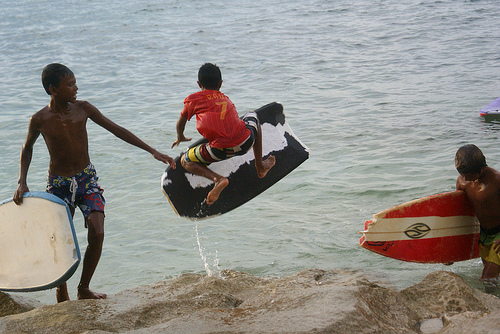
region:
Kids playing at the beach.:
[43, 65, 498, 269]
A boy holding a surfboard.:
[339, 132, 494, 266]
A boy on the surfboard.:
[165, 65, 279, 203]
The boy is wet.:
[17, 74, 127, 206]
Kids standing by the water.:
[30, 80, 463, 327]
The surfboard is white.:
[8, 186, 103, 303]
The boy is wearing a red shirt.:
[188, 85, 245, 140]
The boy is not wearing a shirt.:
[25, 101, 115, 174]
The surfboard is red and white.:
[343, 193, 483, 275]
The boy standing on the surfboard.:
[159, 75, 319, 209]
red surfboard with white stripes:
[356, 188, 484, 263]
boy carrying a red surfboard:
[361, 143, 498, 267]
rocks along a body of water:
[2, 271, 495, 330]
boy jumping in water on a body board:
[160, 63, 310, 220]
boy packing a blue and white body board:
[0, 60, 172, 298]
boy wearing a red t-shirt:
[180, 90, 250, 150]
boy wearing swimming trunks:
[44, 163, 104, 224]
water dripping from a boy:
[191, 219, 225, 279]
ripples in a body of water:
[302, 3, 452, 125]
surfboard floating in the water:
[476, 98, 498, 122]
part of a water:
[345, 46, 375, 121]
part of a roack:
[320, 270, 339, 292]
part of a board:
[381, 210, 421, 280]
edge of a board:
[356, 183, 390, 258]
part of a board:
[221, 159, 258, 216]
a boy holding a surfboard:
[5, 50, 121, 296]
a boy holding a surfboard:
[319, 93, 487, 329]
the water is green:
[249, 42, 354, 108]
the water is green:
[268, 218, 355, 264]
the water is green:
[288, 44, 384, 61]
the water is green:
[99, 41, 200, 71]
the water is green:
[262, 25, 331, 80]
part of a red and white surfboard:
[350, 192, 488, 275]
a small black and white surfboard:
[145, 100, 307, 215]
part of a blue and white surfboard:
[1, 180, 84, 300]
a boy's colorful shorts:
[38, 168, 111, 215]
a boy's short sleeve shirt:
[182, 88, 247, 146]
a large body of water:
[1, 1, 498, 303]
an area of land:
[0, 266, 497, 331]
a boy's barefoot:
[200, 173, 232, 202]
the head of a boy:
[450, 143, 489, 183]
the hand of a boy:
[148, 148, 181, 165]